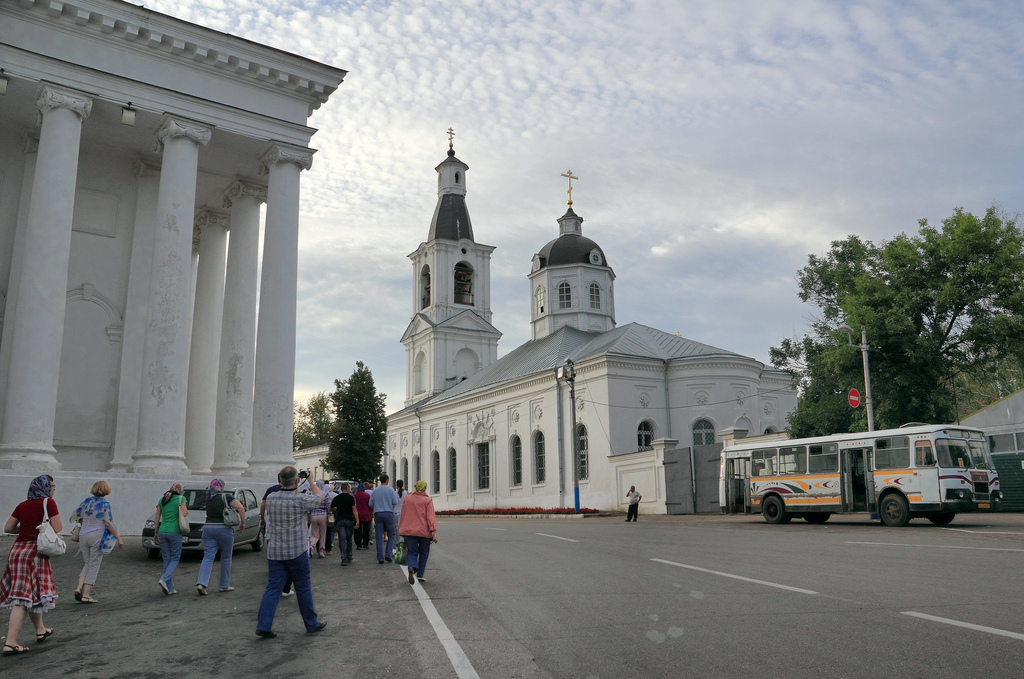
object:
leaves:
[792, 353, 839, 425]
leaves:
[873, 322, 912, 401]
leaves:
[816, 244, 884, 325]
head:
[279, 465, 301, 489]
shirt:
[265, 487, 323, 560]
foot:
[255, 630, 277, 638]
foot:
[309, 621, 328, 632]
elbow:
[302, 488, 322, 510]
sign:
[849, 388, 862, 408]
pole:
[862, 331, 875, 432]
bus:
[718, 422, 1003, 528]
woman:
[154, 483, 190, 595]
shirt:
[156, 494, 188, 532]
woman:
[69, 481, 124, 604]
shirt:
[79, 517, 103, 535]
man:
[329, 482, 361, 566]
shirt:
[331, 493, 356, 526]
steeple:
[556, 190, 583, 238]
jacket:
[399, 491, 438, 539]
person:
[399, 479, 438, 585]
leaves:
[769, 206, 1024, 439]